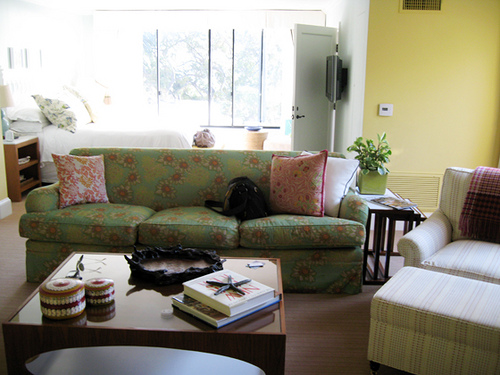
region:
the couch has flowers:
[130, 159, 176, 197]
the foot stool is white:
[412, 286, 452, 306]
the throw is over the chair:
[457, 170, 482, 195]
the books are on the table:
[237, 301, 272, 326]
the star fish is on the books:
[211, 273, 248, 304]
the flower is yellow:
[295, 261, 320, 284]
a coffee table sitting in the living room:
[15, 245, 292, 372]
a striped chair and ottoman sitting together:
[370, 163, 495, 369]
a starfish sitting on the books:
[204, 276, 251, 296]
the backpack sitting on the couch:
[208, 178, 267, 221]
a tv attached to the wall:
[320, 55, 340, 102]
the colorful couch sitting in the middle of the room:
[16, 148, 368, 292]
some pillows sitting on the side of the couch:
[268, 148, 353, 215]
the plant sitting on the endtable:
[353, 135, 394, 195]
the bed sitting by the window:
[1, 70, 197, 152]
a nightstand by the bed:
[5, 133, 46, 190]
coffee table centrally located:
[6, 250, 289, 374]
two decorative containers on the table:
[39, 277, 114, 324]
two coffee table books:
[172, 267, 282, 331]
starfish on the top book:
[207, 276, 254, 296]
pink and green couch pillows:
[31, 93, 324, 215]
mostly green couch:
[17, 148, 365, 295]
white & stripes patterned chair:
[396, 166, 496, 281]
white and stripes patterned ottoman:
[368, 265, 496, 373]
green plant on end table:
[345, 133, 396, 194]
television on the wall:
[325, 53, 350, 103]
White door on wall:
[285, 21, 331, 156]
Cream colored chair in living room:
[396, 163, 498, 280]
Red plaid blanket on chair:
[455, 164, 498, 243]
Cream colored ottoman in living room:
[363, 264, 498, 371]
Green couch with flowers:
[15, 143, 370, 260]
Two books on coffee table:
[165, 267, 282, 330]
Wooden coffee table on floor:
[0, 246, 292, 371]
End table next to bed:
[2, 133, 43, 198]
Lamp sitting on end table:
[2, 81, 18, 144]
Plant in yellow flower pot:
[347, 130, 392, 195]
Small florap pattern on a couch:
[300, 219, 328, 245]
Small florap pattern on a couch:
[295, 254, 335, 284]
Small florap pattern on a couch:
[23, 213, 61, 242]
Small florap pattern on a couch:
[82, 202, 112, 227]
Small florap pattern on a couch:
[100, 145, 137, 175]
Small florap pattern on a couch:
[155, 137, 192, 178]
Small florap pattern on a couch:
[242, 145, 275, 185]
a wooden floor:
[311, 296, 351, 352]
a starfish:
[212, 271, 250, 296]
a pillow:
[270, 151, 330, 207]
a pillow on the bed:
[38, 83, 97, 126]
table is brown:
[116, 295, 148, 320]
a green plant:
[354, 138, 392, 171]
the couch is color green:
[13, 138, 372, 303]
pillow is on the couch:
[47, 148, 117, 215]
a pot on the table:
[343, 125, 400, 210]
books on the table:
[167, 262, 283, 334]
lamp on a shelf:
[0, 73, 45, 195]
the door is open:
[281, 16, 346, 150]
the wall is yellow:
[351, 1, 496, 171]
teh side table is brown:
[356, 186, 428, 289]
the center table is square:
[9, 236, 298, 361]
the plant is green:
[345, 131, 400, 178]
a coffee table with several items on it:
[7, 232, 323, 350]